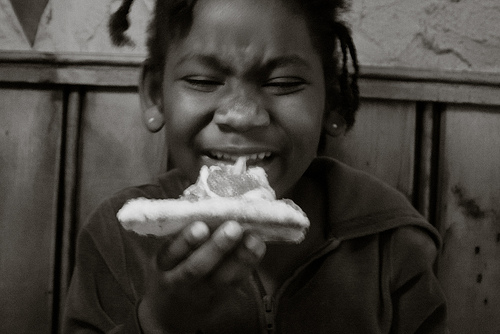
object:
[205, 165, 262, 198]
pepperoni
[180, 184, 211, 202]
pepperoni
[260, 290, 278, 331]
pull tab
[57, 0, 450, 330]
child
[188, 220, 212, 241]
fingernail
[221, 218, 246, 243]
fingernail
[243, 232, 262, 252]
fingernail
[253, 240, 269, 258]
fingernail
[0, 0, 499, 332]
wall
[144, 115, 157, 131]
earring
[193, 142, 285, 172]
mouth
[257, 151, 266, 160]
teeth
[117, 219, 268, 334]
hand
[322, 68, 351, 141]
ear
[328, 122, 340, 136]
earring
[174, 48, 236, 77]
eyebrow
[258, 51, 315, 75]
eyebrow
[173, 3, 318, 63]
forehead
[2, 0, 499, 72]
wall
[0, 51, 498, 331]
paneling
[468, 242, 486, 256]
marks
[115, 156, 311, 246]
pizza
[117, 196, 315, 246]
crust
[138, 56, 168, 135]
ear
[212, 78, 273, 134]
nose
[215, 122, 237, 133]
nostril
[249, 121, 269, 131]
nostril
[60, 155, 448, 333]
sweater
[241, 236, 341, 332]
zipper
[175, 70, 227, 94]
eye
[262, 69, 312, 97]
eye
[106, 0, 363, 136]
hair